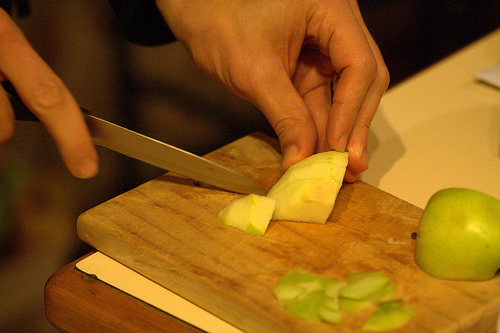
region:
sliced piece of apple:
[262, 144, 358, 232]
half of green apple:
[403, 181, 495, 286]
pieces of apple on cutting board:
[278, 269, 400, 330]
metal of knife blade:
[136, 131, 271, 200]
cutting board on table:
[170, 173, 415, 321]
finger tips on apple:
[272, 124, 377, 179]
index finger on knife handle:
[45, 86, 100, 192]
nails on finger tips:
[330, 129, 370, 172]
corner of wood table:
[16, 265, 86, 330]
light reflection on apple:
[457, 212, 489, 245]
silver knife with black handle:
[2, 80, 272, 198]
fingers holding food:
[264, 78, 387, 182]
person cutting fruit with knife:
[0, 4, 389, 239]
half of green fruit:
[408, 185, 499, 286]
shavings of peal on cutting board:
[268, 265, 413, 331]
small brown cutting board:
[71, 130, 499, 331]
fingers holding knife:
[1, 3, 101, 177]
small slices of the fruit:
[218, 147, 352, 235]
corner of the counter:
[40, 245, 128, 330]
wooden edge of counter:
[40, 245, 210, 331]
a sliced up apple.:
[205, 120, 382, 255]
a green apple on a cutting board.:
[407, 143, 498, 284]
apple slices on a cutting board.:
[260, 206, 424, 332]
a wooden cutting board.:
[78, 132, 498, 332]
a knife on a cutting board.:
[78, 86, 268, 210]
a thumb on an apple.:
[240, 65, 317, 183]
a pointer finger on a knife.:
[35, 96, 117, 188]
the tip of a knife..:
[230, 150, 274, 203]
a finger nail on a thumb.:
[275, 132, 314, 171]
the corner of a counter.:
[36, 255, 153, 325]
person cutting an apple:
[184, 76, 381, 238]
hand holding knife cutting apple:
[23, 74, 344, 224]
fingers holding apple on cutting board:
[229, 72, 408, 254]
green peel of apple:
[274, 266, 439, 331]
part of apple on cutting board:
[404, 191, 499, 313]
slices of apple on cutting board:
[209, 138, 354, 235]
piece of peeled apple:
[204, 192, 274, 241]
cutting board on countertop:
[204, 123, 495, 284]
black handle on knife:
[6, 62, 287, 237]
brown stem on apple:
[400, 201, 437, 253]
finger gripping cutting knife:
[11, 66, 153, 203]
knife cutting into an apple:
[183, 107, 378, 264]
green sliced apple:
[413, 176, 498, 288]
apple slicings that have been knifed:
[268, 257, 422, 331]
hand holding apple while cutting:
[233, 0, 357, 236]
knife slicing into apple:
[65, 0, 313, 305]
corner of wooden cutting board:
[77, 180, 207, 268]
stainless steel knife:
[108, 110, 256, 210]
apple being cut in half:
[265, 135, 357, 239]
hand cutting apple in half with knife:
[12, 3, 410, 272]